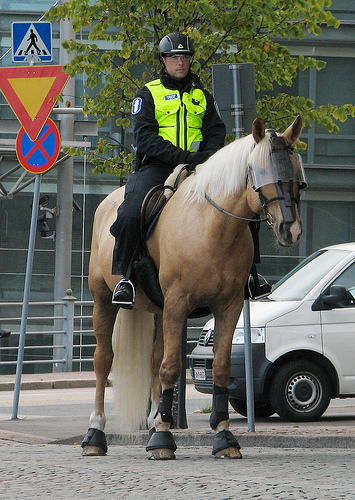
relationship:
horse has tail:
[80, 112, 309, 462] [111, 303, 153, 440]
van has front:
[186, 240, 355, 423] [192, 290, 305, 402]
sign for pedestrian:
[10, 17, 57, 60] [16, 26, 52, 58]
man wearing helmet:
[107, 30, 273, 311] [155, 30, 198, 58]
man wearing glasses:
[107, 30, 273, 311] [159, 52, 200, 63]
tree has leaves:
[49, 3, 348, 409] [41, 3, 354, 181]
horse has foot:
[80, 112, 309, 462] [211, 421, 242, 462]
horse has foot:
[80, 112, 309, 462] [144, 428, 173, 461]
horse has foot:
[80, 112, 309, 462] [81, 415, 111, 458]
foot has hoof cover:
[211, 421, 242, 462] [212, 426, 242, 455]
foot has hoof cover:
[144, 428, 173, 461] [144, 426, 185, 451]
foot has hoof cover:
[81, 415, 111, 458] [77, 424, 110, 450]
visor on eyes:
[245, 149, 310, 188] [255, 162, 302, 183]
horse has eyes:
[80, 112, 309, 462] [255, 162, 302, 183]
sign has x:
[15, 117, 62, 173] [19, 122, 55, 160]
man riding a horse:
[107, 30, 273, 311] [80, 112, 309, 462]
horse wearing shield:
[80, 112, 309, 462] [245, 149, 310, 188]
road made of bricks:
[4, 411, 355, 499] [2, 446, 347, 498]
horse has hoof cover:
[80, 112, 309, 462] [212, 426, 242, 455]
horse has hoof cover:
[80, 112, 309, 462] [144, 426, 185, 451]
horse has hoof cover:
[80, 112, 309, 462] [77, 424, 110, 450]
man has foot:
[107, 30, 273, 311] [114, 263, 138, 309]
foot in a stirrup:
[114, 263, 138, 309] [113, 276, 138, 307]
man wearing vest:
[107, 30, 273, 311] [141, 75, 203, 168]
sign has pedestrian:
[10, 17, 57, 60] [16, 26, 52, 58]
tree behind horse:
[49, 3, 348, 409] [80, 112, 309, 462]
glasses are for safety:
[159, 52, 200, 63] [157, 53, 196, 67]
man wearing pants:
[107, 30, 273, 311] [114, 162, 266, 282]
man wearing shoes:
[107, 30, 273, 311] [114, 281, 134, 310]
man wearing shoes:
[107, 30, 273, 311] [244, 269, 277, 300]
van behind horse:
[186, 240, 355, 423] [80, 112, 309, 462]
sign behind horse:
[10, 17, 57, 60] [80, 112, 309, 462]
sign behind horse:
[0, 61, 72, 139] [80, 112, 309, 462]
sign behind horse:
[15, 117, 62, 173] [80, 112, 309, 462]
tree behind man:
[49, 3, 348, 409] [107, 30, 273, 311]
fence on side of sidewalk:
[8, 296, 209, 371] [0, 364, 109, 392]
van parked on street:
[186, 240, 355, 423] [0, 380, 355, 425]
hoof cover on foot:
[212, 426, 242, 455] [211, 421, 242, 462]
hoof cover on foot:
[144, 426, 185, 451] [144, 428, 173, 461]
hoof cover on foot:
[77, 424, 110, 450] [81, 415, 111, 458]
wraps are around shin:
[258, 191, 305, 246] [268, 214, 306, 244]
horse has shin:
[80, 112, 309, 462] [268, 214, 306, 244]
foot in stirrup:
[114, 263, 138, 309] [113, 276, 138, 307]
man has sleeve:
[107, 30, 273, 311] [130, 88, 155, 151]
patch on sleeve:
[129, 94, 146, 119] [130, 88, 155, 151]